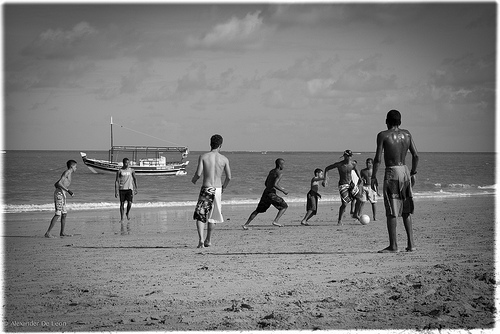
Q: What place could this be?
A: It is a beach.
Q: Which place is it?
A: It is a beach.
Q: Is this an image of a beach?
A: Yes, it is showing a beach.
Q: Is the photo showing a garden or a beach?
A: It is showing a beach.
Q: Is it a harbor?
A: No, it is a beach.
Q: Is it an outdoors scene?
A: Yes, it is outdoors.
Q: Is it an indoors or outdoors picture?
A: It is outdoors.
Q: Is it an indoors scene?
A: No, it is outdoors.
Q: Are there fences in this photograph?
A: No, there are no fences.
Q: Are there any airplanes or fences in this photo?
A: No, there are no fences or airplanes.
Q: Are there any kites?
A: No, there are no kites.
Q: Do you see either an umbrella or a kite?
A: No, there are no kites or umbrellas.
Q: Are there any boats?
A: Yes, there is a boat.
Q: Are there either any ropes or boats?
A: Yes, there is a boat.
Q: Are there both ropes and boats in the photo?
A: No, there is a boat but no ropes.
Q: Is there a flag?
A: No, there are no flags.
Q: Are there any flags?
A: No, there are no flags.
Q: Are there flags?
A: No, there are no flags.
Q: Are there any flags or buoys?
A: No, there are no flags or buoys.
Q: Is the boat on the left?
A: Yes, the boat is on the left of the image.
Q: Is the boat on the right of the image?
A: No, the boat is on the left of the image.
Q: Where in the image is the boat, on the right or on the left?
A: The boat is on the left of the image.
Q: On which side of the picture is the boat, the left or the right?
A: The boat is on the left of the image.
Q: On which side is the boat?
A: The boat is on the left of the image.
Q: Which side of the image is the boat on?
A: The boat is on the left of the image.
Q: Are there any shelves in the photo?
A: No, there are no shelves.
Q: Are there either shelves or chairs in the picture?
A: No, there are no shelves or chairs.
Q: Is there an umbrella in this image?
A: No, there are no umbrellas.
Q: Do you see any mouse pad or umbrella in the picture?
A: No, there are no umbrellas or mouse pads.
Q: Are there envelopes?
A: No, there are no envelopes.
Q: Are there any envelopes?
A: No, there are no envelopes.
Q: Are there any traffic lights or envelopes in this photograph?
A: No, there are no envelopes or traffic lights.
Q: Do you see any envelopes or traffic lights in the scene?
A: No, there are no envelopes or traffic lights.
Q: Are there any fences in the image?
A: No, there are no fences.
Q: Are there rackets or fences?
A: No, there are no fences or rackets.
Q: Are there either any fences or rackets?
A: No, there are no fences or rackets.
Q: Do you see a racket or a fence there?
A: No, there are no fences or rackets.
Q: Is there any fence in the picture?
A: No, there are no fences.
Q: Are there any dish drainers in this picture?
A: No, there are no dish drainers.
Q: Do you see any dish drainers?
A: No, there are no dish drainers.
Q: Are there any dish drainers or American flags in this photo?
A: No, there are no dish drainers or American flags.